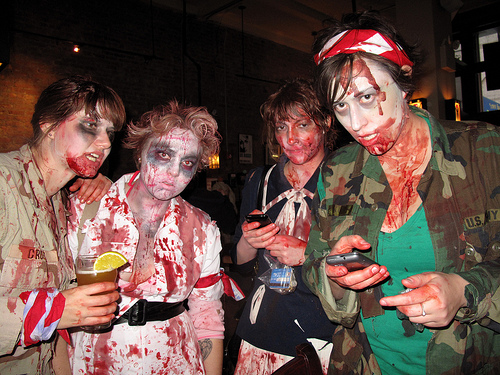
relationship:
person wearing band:
[292, 20, 494, 374] [309, 24, 411, 69]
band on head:
[309, 24, 411, 69] [311, 46, 414, 162]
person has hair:
[292, 12, 499, 374] [322, 54, 353, 110]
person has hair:
[226, 80, 343, 373] [262, 78, 332, 155]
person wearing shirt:
[253, 80, 326, 273] [249, 161, 336, 349]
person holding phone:
[292, 12, 499, 374] [323, 251, 379, 277]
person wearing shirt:
[292, 12, 499, 374] [371, 207, 451, 368]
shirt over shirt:
[424, 110, 498, 326] [371, 207, 451, 368]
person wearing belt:
[61, 95, 227, 373] [107, 285, 193, 330]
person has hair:
[0, 74, 127, 374] [28, 74, 125, 128]